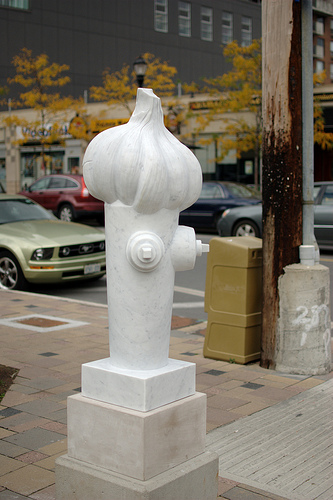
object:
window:
[177, 8, 190, 20]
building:
[0, 0, 332, 193]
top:
[80, 86, 203, 214]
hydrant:
[54, 87, 219, 499]